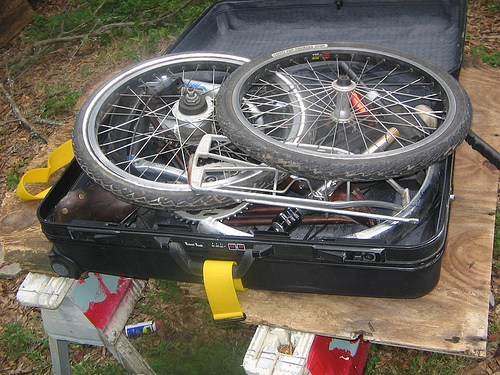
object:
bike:
[70, 41, 474, 245]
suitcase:
[33, 0, 468, 301]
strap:
[201, 258, 249, 325]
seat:
[52, 184, 134, 225]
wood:
[0, 51, 500, 361]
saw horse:
[15, 272, 158, 375]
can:
[123, 319, 157, 338]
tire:
[212, 38, 472, 184]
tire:
[71, 48, 321, 214]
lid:
[160, 0, 467, 89]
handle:
[166, 242, 256, 280]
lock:
[184, 241, 247, 252]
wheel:
[48, 254, 78, 277]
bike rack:
[188, 133, 413, 210]